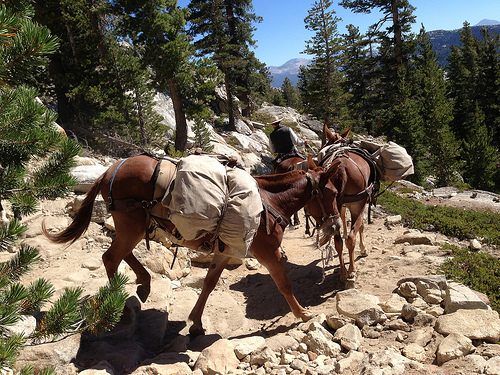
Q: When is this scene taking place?
A: Daytime.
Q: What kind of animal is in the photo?
A: Horse.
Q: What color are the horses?
A: Brown.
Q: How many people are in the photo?
A: One.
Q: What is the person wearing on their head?
A: Hat.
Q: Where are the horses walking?
A: Mountain.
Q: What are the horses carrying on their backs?
A: Bags.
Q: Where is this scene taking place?
A: On a mountain.